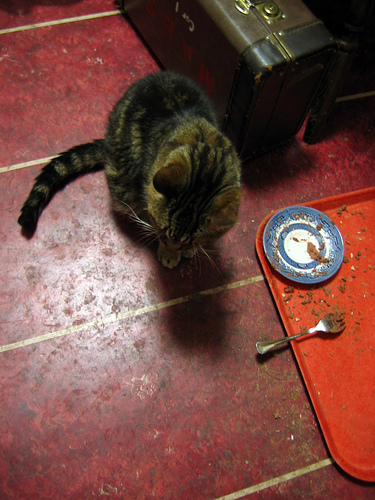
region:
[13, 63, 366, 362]
A cat that has finished eating.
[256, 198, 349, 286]
A white and blue saucer.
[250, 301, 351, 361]
A silver fork laying on a tray.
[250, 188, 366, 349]
Bits of cat food on the tray.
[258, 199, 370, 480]
An orange tray on the floor.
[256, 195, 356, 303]
The saucer is sitting on the tray.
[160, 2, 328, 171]
Part of an older suitcase.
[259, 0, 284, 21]
The lock on top of a suitcase.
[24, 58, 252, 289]
A cat with black stripes.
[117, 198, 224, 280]
Whiskers on the cat's face.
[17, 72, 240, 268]
a cat on the floor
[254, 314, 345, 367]
a fork in a tray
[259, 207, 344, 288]
a saucer on a try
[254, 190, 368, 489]
a orange tray on the floor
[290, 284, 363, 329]
cat food on the tray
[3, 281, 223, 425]
a red floor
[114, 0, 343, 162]
a suit case on the floor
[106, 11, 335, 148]
a brown suit case on the floor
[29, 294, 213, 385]
white strip between the tiles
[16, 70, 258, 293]
a black and tan cat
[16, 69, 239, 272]
cat sitting on the floor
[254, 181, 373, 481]
red tray on the floor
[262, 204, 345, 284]
small blue and white plate on tray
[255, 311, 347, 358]
fork on red tray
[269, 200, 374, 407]
crumbs on the tray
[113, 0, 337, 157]
suitcase behind the cat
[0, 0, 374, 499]
red floor under the cat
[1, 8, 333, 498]
white lines on the floor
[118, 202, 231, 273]
white whiskers on the cat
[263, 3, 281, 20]
brass lock on suitcase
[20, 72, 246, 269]
a black striped cat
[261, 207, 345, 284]
a small white plate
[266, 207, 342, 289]
a plate with cat food on it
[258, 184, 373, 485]
a dirty orange lunch tray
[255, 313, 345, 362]
a small silver dirty fork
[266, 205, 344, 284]
a plate with blue decal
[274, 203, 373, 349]
cat food on tray and plate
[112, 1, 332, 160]
a hard brown leather briefcase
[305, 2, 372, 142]
a dark wooden chair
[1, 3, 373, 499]
large red rectangle tiles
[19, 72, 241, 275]
a black cat with stripes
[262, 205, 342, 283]
a small round plate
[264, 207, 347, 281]
a plate with blue design edges and center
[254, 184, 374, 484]
an orange lunch tray with food on it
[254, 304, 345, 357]
a shiny metal dirty fork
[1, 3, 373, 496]
a dark red floor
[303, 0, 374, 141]
a dark brown wooden chair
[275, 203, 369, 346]
cat food